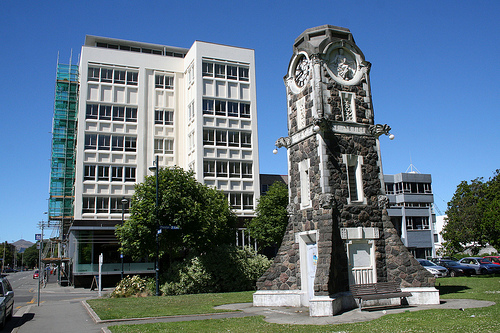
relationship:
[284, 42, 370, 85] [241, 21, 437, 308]
clock on tower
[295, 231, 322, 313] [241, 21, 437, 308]
door on tower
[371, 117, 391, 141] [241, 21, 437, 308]
statue on tower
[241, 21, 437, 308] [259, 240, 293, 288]
tower of stone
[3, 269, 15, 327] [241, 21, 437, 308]
car parked near tower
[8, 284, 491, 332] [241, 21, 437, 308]
sidewalk around tower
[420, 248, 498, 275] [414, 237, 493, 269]
cars in line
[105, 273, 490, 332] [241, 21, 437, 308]
grass near tower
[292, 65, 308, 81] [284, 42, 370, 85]
face of clock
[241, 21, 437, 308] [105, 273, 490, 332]
tower in grass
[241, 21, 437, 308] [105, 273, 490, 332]
tower on grass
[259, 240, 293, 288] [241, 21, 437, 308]
stone on tower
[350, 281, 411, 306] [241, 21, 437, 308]
bench by tower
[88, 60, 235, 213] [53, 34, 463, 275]
windows on building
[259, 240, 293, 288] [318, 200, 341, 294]
stone on pillar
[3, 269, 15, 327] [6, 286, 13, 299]
car has mirror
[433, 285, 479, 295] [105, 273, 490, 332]
shadow on grass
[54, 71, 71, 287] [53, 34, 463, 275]
fire escape on building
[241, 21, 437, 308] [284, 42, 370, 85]
tower has clock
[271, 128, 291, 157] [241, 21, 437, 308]
light on tower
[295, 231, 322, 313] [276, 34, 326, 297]
door on side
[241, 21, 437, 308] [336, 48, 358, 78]
tower has figure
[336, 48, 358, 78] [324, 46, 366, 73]
figure on face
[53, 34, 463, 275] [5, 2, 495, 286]
building in background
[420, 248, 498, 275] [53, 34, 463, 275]
cars near building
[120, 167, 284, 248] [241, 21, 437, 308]
trees near tower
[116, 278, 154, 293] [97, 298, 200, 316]
flowers on ground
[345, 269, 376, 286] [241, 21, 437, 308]
rail on tower